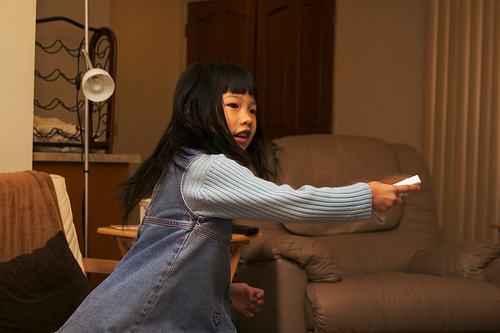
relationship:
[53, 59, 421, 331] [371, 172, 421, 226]
girl playing wii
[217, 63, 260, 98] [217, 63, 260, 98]
bangs on bangs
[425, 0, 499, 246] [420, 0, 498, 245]
curtains on window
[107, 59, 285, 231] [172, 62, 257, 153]
hair on head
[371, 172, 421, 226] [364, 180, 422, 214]
wii controller in hand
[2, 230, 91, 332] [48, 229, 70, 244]
pillow has corner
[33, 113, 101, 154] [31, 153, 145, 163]
linen on counter top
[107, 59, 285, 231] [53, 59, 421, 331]
hair on girl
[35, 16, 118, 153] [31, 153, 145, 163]
wine rack on counter top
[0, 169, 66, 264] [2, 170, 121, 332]
blanket on couch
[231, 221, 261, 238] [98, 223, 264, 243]
tv remote on table top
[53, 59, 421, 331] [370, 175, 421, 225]
girl holding cloth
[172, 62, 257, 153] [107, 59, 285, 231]
head with hair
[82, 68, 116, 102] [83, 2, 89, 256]
lampshade on shand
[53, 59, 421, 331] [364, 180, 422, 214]
girl with hand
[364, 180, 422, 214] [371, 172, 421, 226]
hand holding object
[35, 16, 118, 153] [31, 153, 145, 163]
rack on top of stand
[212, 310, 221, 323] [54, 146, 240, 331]
badge on dress